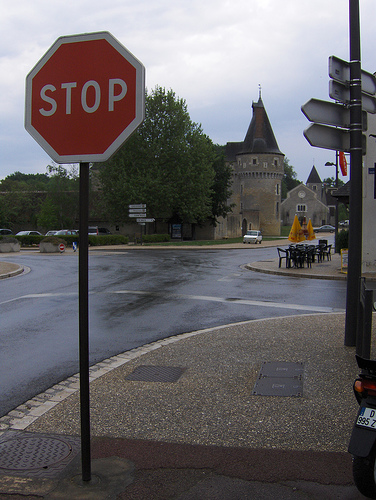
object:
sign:
[24, 31, 145, 164]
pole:
[80, 161, 92, 479]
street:
[2, 235, 375, 431]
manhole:
[0, 437, 68, 473]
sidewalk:
[0, 310, 365, 499]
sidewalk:
[245, 252, 350, 281]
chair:
[276, 244, 288, 267]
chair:
[319, 238, 329, 248]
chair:
[324, 244, 333, 259]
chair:
[292, 246, 306, 268]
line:
[120, 288, 350, 315]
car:
[242, 228, 263, 245]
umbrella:
[286, 213, 307, 245]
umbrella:
[305, 218, 313, 241]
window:
[251, 157, 257, 166]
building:
[216, 85, 286, 241]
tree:
[97, 88, 215, 227]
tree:
[210, 152, 234, 226]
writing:
[36, 77, 126, 120]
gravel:
[28, 313, 360, 451]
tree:
[36, 175, 76, 224]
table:
[291, 247, 310, 254]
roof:
[239, 98, 282, 155]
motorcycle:
[346, 356, 376, 500]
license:
[354, 405, 375, 430]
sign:
[327, 54, 375, 93]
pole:
[344, 2, 363, 347]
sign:
[330, 79, 375, 113]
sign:
[300, 99, 368, 129]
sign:
[303, 123, 367, 154]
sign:
[136, 216, 156, 223]